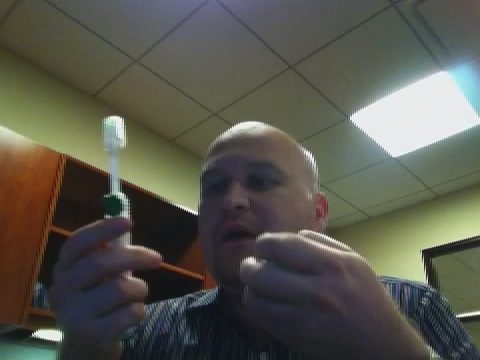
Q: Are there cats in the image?
A: No, there are no cats.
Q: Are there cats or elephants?
A: No, there are no cats or elephants.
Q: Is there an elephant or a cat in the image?
A: No, there are no cats or elephants.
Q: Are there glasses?
A: No, there are no glasses.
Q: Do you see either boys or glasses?
A: No, there are no glasses or boys.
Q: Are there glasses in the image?
A: No, there are no glasses.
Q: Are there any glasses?
A: No, there are no glasses.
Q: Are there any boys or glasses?
A: No, there are no glasses or boys.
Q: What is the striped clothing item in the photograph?
A: The clothing item is a shirt.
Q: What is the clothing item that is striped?
A: The clothing item is a shirt.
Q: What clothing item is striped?
A: The clothing item is a shirt.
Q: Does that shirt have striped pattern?
A: Yes, the shirt is striped.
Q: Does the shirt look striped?
A: Yes, the shirt is striped.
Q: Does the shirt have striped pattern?
A: Yes, the shirt is striped.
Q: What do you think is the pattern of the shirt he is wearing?
A: The shirt is striped.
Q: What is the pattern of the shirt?
A: The shirt is striped.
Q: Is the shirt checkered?
A: No, the shirt is striped.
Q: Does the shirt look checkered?
A: No, the shirt is striped.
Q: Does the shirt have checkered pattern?
A: No, the shirt is striped.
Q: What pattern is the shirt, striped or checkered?
A: The shirt is striped.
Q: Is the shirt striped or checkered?
A: The shirt is striped.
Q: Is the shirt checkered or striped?
A: The shirt is striped.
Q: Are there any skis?
A: No, there are no skis.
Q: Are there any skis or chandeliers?
A: No, there are no skis or chandeliers.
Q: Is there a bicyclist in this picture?
A: No, there are no cyclists.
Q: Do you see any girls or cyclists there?
A: No, there are no cyclists or girls.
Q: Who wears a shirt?
A: The man wears a shirt.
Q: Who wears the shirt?
A: The man wears a shirt.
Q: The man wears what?
A: The man wears a shirt.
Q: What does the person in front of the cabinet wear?
A: The man wears a shirt.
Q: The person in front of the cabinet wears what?
A: The man wears a shirt.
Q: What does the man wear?
A: The man wears a shirt.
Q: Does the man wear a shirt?
A: Yes, the man wears a shirt.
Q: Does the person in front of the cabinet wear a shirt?
A: Yes, the man wears a shirt.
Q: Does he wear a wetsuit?
A: No, the man wears a shirt.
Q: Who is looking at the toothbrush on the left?
A: The man is looking at the toothbrush.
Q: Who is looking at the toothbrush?
A: The man is looking at the toothbrush.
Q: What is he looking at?
A: The man is looking at the toothbrush.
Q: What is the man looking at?
A: The man is looking at the toothbrush.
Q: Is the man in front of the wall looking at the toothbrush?
A: Yes, the man is looking at the toothbrush.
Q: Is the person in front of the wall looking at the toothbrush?
A: Yes, the man is looking at the toothbrush.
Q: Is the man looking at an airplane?
A: No, the man is looking at the toothbrush.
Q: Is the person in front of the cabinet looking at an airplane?
A: No, the man is looking at the toothbrush.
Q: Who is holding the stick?
A: The man is holding the stick.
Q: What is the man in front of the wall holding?
A: The man is holding the stick.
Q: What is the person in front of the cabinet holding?
A: The man is holding the stick.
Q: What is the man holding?
A: The man is holding the stick.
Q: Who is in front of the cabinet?
A: The man is in front of the cabinet.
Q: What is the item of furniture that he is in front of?
A: The piece of furniture is a cabinet.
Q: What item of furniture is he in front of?
A: The man is in front of the cabinet.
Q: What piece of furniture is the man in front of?
A: The man is in front of the cabinet.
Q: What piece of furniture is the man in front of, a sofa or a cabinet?
A: The man is in front of a cabinet.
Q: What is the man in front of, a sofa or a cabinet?
A: The man is in front of a cabinet.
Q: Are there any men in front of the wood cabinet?
A: Yes, there is a man in front of the cabinet.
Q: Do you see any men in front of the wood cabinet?
A: Yes, there is a man in front of the cabinet.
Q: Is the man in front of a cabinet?
A: Yes, the man is in front of a cabinet.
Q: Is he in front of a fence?
A: No, the man is in front of a cabinet.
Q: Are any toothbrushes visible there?
A: Yes, there is a toothbrush.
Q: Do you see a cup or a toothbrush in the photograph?
A: Yes, there is a toothbrush.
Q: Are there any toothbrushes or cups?
A: Yes, there is a toothbrush.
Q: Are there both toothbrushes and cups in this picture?
A: No, there is a toothbrush but no cups.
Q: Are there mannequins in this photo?
A: No, there are no mannequins.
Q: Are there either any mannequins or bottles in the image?
A: No, there are no mannequins or bottles.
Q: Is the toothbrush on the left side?
A: Yes, the toothbrush is on the left of the image.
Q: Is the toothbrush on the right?
A: No, the toothbrush is on the left of the image.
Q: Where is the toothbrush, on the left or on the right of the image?
A: The toothbrush is on the left of the image.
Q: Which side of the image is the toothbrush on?
A: The toothbrush is on the left of the image.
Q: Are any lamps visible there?
A: No, there are no lamps.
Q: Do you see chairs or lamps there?
A: No, there are no lamps or chairs.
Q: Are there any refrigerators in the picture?
A: No, there are no refrigerators.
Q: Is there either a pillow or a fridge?
A: No, there are no refrigerators or pillows.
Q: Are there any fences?
A: No, there are no fences.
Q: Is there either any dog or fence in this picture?
A: No, there are no fences or dogs.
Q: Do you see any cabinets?
A: Yes, there is a cabinet.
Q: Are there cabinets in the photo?
A: Yes, there is a cabinet.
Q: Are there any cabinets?
A: Yes, there is a cabinet.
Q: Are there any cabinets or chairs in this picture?
A: Yes, there is a cabinet.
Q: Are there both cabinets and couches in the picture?
A: No, there is a cabinet but no couches.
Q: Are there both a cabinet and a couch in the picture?
A: No, there is a cabinet but no couches.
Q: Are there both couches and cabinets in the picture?
A: No, there is a cabinet but no couches.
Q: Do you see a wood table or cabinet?
A: Yes, there is a wood cabinet.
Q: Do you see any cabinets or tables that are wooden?
A: Yes, the cabinet is wooden.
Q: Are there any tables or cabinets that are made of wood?
A: Yes, the cabinet is made of wood.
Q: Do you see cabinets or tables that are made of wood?
A: Yes, the cabinet is made of wood.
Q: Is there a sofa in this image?
A: No, there are no sofas.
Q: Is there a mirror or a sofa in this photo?
A: No, there are no sofas or mirrors.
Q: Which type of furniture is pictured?
A: The furniture is a cabinet.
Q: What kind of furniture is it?
A: The piece of furniture is a cabinet.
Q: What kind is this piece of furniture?
A: This is a cabinet.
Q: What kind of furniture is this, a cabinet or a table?
A: This is a cabinet.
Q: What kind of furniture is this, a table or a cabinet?
A: This is a cabinet.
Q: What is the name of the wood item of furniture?
A: The piece of furniture is a cabinet.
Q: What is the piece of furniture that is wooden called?
A: The piece of furniture is a cabinet.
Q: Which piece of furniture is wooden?
A: The piece of furniture is a cabinet.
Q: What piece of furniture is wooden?
A: The piece of furniture is a cabinet.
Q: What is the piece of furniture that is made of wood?
A: The piece of furniture is a cabinet.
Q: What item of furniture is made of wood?
A: The piece of furniture is a cabinet.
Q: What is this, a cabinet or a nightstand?
A: This is a cabinet.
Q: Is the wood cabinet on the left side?
A: Yes, the cabinet is on the left of the image.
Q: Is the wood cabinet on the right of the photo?
A: No, the cabinet is on the left of the image.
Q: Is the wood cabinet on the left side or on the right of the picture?
A: The cabinet is on the left of the image.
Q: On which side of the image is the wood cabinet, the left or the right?
A: The cabinet is on the left of the image.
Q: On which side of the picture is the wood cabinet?
A: The cabinet is on the left of the image.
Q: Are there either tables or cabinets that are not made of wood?
A: No, there is a cabinet but it is made of wood.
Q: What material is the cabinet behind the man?
A: The cabinet is made of wood.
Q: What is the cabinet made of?
A: The cabinet is made of wood.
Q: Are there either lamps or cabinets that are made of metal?
A: No, there is a cabinet but it is made of wood.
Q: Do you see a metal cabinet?
A: No, there is a cabinet but it is made of wood.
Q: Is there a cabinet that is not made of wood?
A: No, there is a cabinet but it is made of wood.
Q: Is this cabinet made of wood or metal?
A: The cabinet is made of wood.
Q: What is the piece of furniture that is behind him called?
A: The piece of furniture is a cabinet.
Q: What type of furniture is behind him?
A: The piece of furniture is a cabinet.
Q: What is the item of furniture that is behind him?
A: The piece of furniture is a cabinet.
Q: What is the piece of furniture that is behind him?
A: The piece of furniture is a cabinet.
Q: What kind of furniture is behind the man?
A: The piece of furniture is a cabinet.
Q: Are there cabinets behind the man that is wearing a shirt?
A: Yes, there is a cabinet behind the man.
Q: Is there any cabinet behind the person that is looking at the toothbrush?
A: Yes, there is a cabinet behind the man.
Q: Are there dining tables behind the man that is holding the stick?
A: No, there is a cabinet behind the man.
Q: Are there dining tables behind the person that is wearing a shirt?
A: No, there is a cabinet behind the man.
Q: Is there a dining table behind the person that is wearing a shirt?
A: No, there is a cabinet behind the man.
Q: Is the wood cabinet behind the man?
A: Yes, the cabinet is behind the man.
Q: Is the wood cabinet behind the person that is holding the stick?
A: Yes, the cabinet is behind the man.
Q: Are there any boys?
A: No, there are no boys.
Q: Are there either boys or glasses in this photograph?
A: No, there are no boys or glasses.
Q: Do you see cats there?
A: No, there are no cats.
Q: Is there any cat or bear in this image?
A: No, there are no cats or bears.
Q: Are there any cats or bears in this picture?
A: No, there are no cats or bears.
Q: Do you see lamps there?
A: No, there are no lamps.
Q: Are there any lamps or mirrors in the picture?
A: No, there are no lamps or mirrors.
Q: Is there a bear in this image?
A: No, there are no bears.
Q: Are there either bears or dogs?
A: No, there are no bears or dogs.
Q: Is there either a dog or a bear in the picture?
A: No, there are no bears or dogs.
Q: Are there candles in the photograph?
A: No, there are no candles.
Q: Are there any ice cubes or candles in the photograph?
A: No, there are no candles or ice cubes.